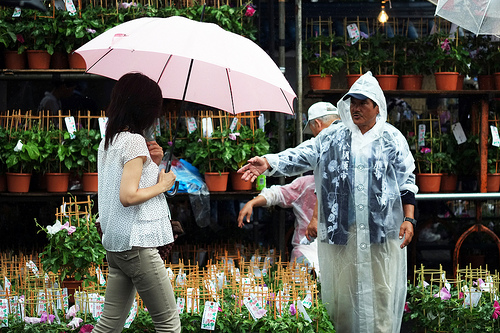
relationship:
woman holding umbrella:
[91, 67, 189, 331] [69, 12, 304, 199]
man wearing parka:
[234, 67, 420, 332] [261, 69, 418, 332]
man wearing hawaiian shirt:
[234, 67, 420, 332] [276, 124, 409, 243]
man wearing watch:
[234, 67, 420, 332] [399, 213, 421, 225]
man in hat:
[299, 96, 340, 139] [298, 97, 339, 135]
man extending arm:
[234, 67, 420, 332] [234, 133, 321, 185]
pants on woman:
[86, 231, 183, 331] [91, 67, 189, 331]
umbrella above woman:
[69, 12, 304, 199] [91, 67, 189, 331]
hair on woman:
[103, 69, 165, 150] [91, 67, 189, 331]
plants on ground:
[3, 242, 499, 332] [7, 331, 496, 332]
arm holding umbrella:
[120, 133, 175, 209] [69, 12, 304, 199]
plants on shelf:
[302, 11, 499, 90] [302, 86, 499, 100]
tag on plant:
[346, 22, 362, 44] [340, 16, 375, 91]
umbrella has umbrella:
[69, 12, 304, 199] [69, 12, 304, 199]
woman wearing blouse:
[91, 67, 189, 331] [92, 127, 179, 249]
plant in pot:
[340, 16, 375, 91] [344, 72, 365, 89]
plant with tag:
[340, 16, 375, 91] [346, 22, 362, 44]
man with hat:
[299, 96, 340, 139] [298, 97, 339, 135]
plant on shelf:
[340, 16, 375, 91] [302, 86, 499, 100]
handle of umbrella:
[163, 159, 180, 198] [69, 12, 304, 199]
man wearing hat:
[299, 96, 340, 139] [298, 97, 339, 135]